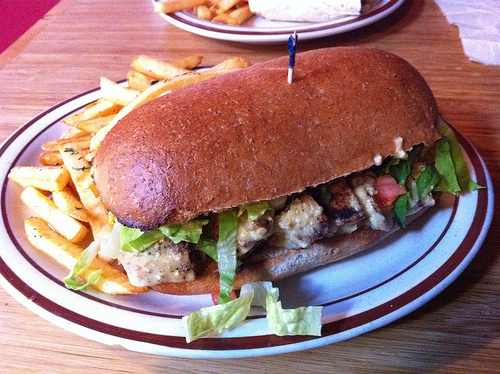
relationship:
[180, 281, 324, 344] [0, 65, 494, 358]
lettuce on plate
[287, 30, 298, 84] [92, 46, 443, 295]
toothpick in bun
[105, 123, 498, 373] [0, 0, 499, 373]
shadow on table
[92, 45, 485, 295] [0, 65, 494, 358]
sandwich on plate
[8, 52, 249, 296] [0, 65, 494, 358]
fries on plate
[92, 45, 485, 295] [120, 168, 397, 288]
sandwich with meat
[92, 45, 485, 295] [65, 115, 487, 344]
sandwich with lettuce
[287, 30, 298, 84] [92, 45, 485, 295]
toothpick in sandwich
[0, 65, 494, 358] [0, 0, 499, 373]
plate on table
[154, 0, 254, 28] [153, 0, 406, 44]
fries on plate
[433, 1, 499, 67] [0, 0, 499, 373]
napkin on table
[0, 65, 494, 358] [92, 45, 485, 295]
plate with sandwich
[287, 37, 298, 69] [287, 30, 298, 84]
end of toothpick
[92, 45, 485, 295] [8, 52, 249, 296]
sandwich with fries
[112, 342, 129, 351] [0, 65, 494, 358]
chip on plate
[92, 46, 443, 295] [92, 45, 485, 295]
bun on sandwich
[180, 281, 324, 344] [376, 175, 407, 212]
lettuce and tomato